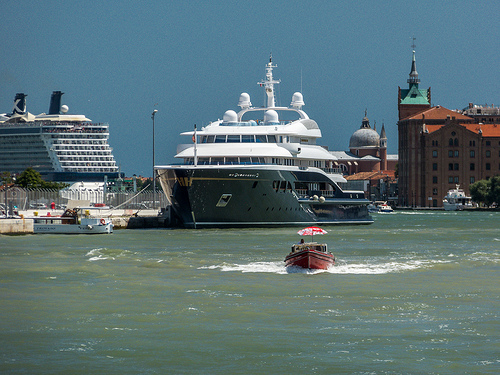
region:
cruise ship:
[162, 65, 353, 222]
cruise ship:
[17, 82, 122, 213]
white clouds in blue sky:
[47, 19, 105, 54]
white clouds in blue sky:
[334, 13, 369, 34]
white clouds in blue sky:
[332, 29, 379, 91]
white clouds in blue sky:
[331, 26, 399, 68]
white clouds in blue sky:
[441, 18, 485, 70]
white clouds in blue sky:
[98, 26, 139, 78]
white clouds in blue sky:
[145, 46, 215, 103]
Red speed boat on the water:
[282, 248, 337, 278]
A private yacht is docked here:
[155, 52, 376, 224]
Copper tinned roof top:
[399, 84, 429, 103]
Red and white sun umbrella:
[297, 225, 327, 240]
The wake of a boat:
[220, 261, 431, 275]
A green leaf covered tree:
[468, 176, 498, 207]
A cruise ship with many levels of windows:
[0, 89, 122, 198]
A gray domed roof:
[349, 128, 384, 148]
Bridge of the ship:
[195, 126, 292, 146]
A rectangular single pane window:
[240, 133, 257, 145]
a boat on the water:
[283, 224, 338, 276]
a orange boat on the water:
[279, 223, 334, 280]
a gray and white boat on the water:
[154, 53, 377, 235]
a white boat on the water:
[28, 210, 113, 241]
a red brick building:
[395, 34, 499, 203]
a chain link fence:
[4, 183, 132, 210]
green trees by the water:
[471, 169, 497, 209]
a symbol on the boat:
[214, 190, 231, 207]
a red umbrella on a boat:
[283, 218, 334, 280]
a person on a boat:
[298, 237, 311, 252]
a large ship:
[154, 52, 372, 227]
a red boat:
[282, 245, 332, 272]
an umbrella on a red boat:
[287, 223, 331, 273]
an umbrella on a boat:
[295, 224, 328, 244]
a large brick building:
[398, 35, 498, 208]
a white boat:
[33, 203, 110, 232]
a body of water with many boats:
[4, 207, 498, 367]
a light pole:
[149, 104, 159, 214]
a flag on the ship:
[189, 121, 200, 144]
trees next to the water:
[467, 180, 498, 212]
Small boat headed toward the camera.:
[278, 221, 340, 277]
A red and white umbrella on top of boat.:
[296, 221, 327, 243]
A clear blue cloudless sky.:
[1, 3, 496, 103]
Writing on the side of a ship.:
[225, 170, 262, 180]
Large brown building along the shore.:
[392, 33, 499, 209]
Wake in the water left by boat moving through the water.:
[194, 243, 444, 288]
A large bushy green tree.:
[468, 172, 498, 214]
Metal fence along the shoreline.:
[0, 187, 166, 209]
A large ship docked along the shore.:
[148, 44, 381, 226]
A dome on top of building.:
[341, 105, 393, 150]